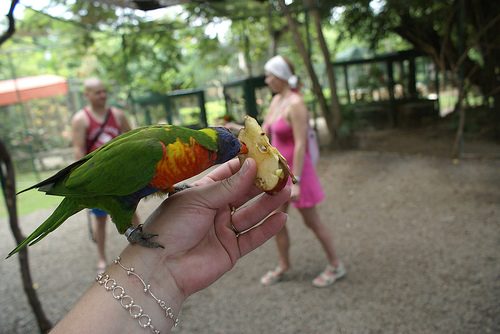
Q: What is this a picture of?
A: Bird.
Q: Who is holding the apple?
A: A woman.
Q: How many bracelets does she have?
A: 2.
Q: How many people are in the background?
A: 2.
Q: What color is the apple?
A: Red.